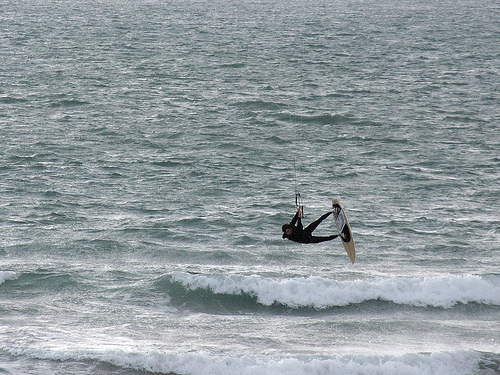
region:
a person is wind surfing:
[231, 137, 378, 279]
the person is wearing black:
[272, 187, 367, 264]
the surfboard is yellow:
[319, 192, 367, 268]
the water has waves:
[11, 230, 496, 372]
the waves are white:
[162, 255, 499, 341]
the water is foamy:
[5, 272, 492, 372]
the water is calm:
[2, 0, 499, 210]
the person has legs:
[283, 189, 358, 267]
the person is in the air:
[248, 185, 393, 303]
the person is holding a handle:
[273, 177, 370, 276]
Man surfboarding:
[276, 157, 361, 268]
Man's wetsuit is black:
[280, 227, 336, 246]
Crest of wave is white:
[159, 255, 487, 327]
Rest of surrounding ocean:
[17, 35, 497, 197]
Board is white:
[334, 183, 354, 270]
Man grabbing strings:
[285, 32, 307, 209]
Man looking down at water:
[278, 222, 295, 239]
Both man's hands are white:
[294, 205, 304, 219]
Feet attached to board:
[326, 195, 361, 260]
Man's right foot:
[337, 227, 351, 241]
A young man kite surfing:
[181, 130, 373, 271]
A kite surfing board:
[326, 195, 368, 270]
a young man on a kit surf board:
[259, 208, 334, 255]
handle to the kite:
[285, 194, 316, 220]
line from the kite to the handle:
[249, 0, 369, 219]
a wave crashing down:
[132, 257, 497, 333]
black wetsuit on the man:
[281, 213, 338, 248]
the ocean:
[19, 6, 491, 353]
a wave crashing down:
[93, 338, 486, 373]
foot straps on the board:
[326, 203, 351, 245]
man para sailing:
[260, 185, 332, 256]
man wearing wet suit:
[278, 207, 328, 251]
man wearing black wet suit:
[268, 207, 333, 252]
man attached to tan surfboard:
[330, 197, 360, 259]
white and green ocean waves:
[6, 221, 211, 364]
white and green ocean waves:
[210, 265, 476, 358]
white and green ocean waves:
[381, 25, 470, 296]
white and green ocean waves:
[3, 7, 268, 281]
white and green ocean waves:
[207, 17, 454, 139]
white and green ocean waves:
[213, 116, 428, 186]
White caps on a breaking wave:
[144, 251, 494, 313]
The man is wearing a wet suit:
[258, 202, 353, 249]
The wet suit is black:
[270, 199, 350, 258]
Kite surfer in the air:
[252, 182, 375, 265]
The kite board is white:
[323, 185, 362, 271]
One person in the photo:
[4, 4, 489, 369]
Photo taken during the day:
[9, 6, 491, 368]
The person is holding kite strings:
[262, 5, 312, 227]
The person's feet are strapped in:
[325, 187, 362, 264]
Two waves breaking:
[1, 221, 493, 368]